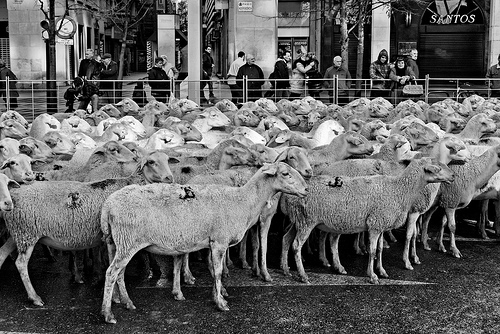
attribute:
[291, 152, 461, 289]
sheep — standing, in a group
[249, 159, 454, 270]
sheep — white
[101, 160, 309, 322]
sheep — in a group, standing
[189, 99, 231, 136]
sheep — white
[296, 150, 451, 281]
sheep — white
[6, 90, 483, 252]
sheep — herd, standing around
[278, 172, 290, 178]
goat blackeye — small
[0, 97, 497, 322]
sheep group — in a group, standing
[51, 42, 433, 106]
people — group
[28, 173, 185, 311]
sheep — white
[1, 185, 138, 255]
hair — fluffy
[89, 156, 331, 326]
sheep — white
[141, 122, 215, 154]
sheep — standing, in a group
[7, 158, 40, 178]
head — turned, to the side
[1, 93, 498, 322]
sheep — standing, in a group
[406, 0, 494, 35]
sign — white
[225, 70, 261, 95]
jacket — black